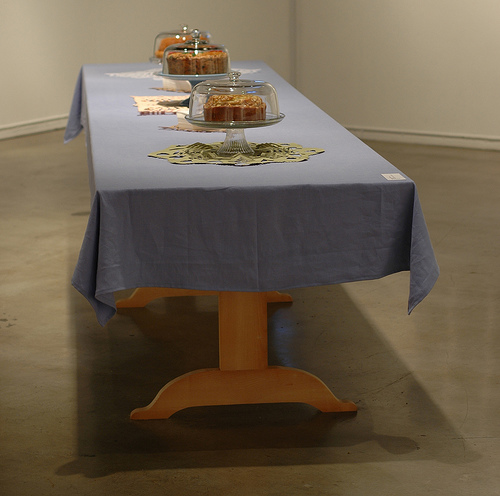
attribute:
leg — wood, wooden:
[130, 290, 360, 422]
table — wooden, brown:
[82, 61, 414, 420]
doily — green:
[148, 139, 323, 168]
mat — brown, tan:
[160, 114, 239, 134]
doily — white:
[105, 65, 261, 83]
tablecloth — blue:
[60, 58, 439, 330]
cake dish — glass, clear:
[185, 69, 286, 157]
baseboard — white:
[344, 122, 499, 152]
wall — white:
[292, 2, 499, 137]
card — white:
[381, 171, 405, 183]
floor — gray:
[3, 124, 499, 496]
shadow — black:
[55, 228, 477, 478]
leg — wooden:
[116, 281, 294, 310]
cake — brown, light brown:
[204, 93, 266, 120]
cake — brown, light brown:
[168, 50, 228, 76]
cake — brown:
[157, 34, 206, 58]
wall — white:
[1, 1, 299, 126]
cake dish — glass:
[153, 29, 241, 107]